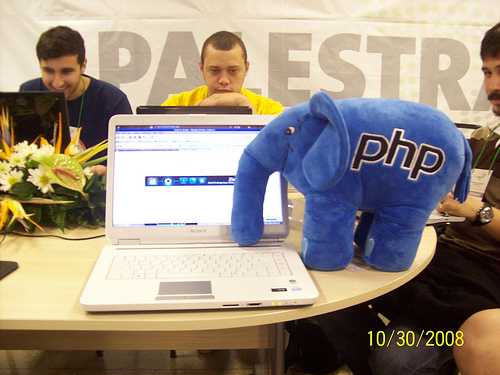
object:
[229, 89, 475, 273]
stuffed animal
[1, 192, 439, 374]
table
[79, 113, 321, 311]
laptop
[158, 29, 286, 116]
man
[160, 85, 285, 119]
shirt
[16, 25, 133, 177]
man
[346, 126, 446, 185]
letters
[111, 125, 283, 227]
screen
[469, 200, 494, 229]
watch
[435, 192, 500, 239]
arm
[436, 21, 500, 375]
man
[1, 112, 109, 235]
flower arrangement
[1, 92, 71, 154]
laptop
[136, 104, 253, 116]
laptop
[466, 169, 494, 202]
name tag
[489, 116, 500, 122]
neck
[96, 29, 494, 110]
letters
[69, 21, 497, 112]
banner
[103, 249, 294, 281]
keyboard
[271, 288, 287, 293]
lable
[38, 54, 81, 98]
face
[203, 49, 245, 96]
face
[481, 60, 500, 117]
face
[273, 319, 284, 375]
post